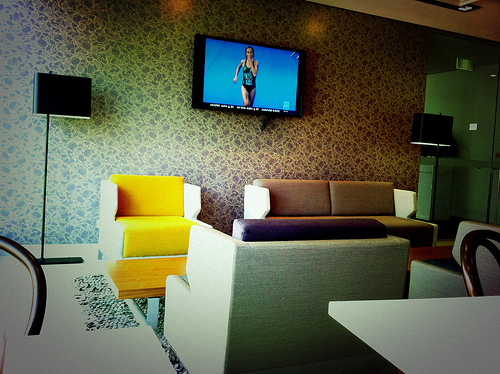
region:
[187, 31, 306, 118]
a flat screen television hangs on the wall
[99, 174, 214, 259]
a yellow chair to the left of a brown loveseat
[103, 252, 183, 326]
a coffee table in front of the chair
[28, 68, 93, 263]
a black floor lamp to the left of the chair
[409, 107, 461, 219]
a fllor lamp to the right of the loveseat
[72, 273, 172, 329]
a rug under the coffee table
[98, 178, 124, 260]
the arms of the yellow chair are tan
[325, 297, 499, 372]
a wooden chair behind a white table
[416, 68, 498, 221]
a green armoire next to a floor lamp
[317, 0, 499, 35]
part of the ceiling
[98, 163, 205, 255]
a bright yellow chair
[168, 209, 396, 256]
a purple cushion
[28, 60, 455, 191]
two black lights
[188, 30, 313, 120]
a flat screen tv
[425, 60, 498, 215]
green colored cabinets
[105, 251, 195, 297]
wood coffee table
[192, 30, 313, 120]
girl in swimsuit on tv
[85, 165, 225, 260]
a chair against the wall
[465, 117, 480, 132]
a white outlet on the cabinet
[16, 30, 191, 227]
wallpaper that looks like scales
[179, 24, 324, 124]
Television is mounted on wall.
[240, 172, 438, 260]
Loveseat beneath television has tan fabric.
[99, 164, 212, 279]
Chair beneath television has yellow fabric.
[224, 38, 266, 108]
Woman wearing swimsuit on television.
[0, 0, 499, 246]
Wall is covered with wallpaper.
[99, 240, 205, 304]
Table top is made from wood.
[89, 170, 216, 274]
Chair frame is white.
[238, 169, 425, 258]
Loveseat frame is white.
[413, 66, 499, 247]
Cabinets on wall to the right.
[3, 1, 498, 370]
Room is dimly lit.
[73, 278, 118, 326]
Small rug to the left of the yellow chair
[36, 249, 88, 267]
Black rectangular base on the floor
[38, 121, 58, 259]
Thin black post attached to the rectangular base on the floor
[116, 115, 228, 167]
Patterned wallpaper above the furniture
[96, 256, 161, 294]
Wood top of the table in the middle of the furniture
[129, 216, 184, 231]
Seat of the bright yellow chair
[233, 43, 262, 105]
Runner on the television screen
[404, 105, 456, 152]
Black lamp on the right side of the room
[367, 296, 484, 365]
Surface of the white item in the foreground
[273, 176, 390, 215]
Brown cushions on the back of the couch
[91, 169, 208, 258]
a yellow and white chair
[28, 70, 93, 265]
there is a black box on the wall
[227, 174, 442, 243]
brown two pillow chair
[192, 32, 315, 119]
there is a TV on on the wall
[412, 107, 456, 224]
there is a black lamp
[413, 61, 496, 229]
there is some green boxes in the coiner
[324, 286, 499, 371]
there is a gray table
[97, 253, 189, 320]
there the is a yellow table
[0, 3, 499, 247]
there are a spots on the wall